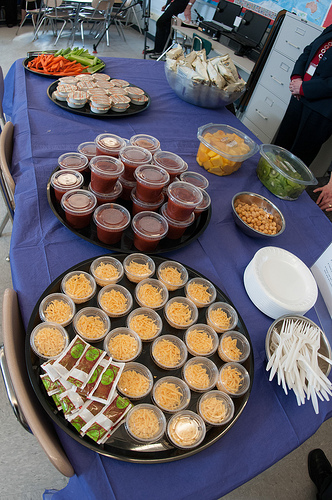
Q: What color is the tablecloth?
A: Purple.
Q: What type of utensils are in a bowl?
A: Forks.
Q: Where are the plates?
A: On the table.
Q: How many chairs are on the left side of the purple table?
A: Three.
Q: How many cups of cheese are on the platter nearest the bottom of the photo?
A: Twenty four.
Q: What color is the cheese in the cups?
A: Orange.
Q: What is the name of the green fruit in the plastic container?
A: Kiwi.